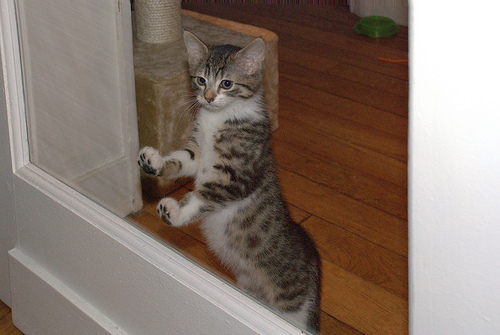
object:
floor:
[112, 1, 404, 334]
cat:
[135, 32, 319, 330]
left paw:
[156, 194, 178, 228]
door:
[2, 0, 415, 334]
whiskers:
[176, 87, 205, 118]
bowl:
[350, 15, 396, 40]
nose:
[204, 92, 216, 103]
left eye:
[220, 80, 234, 92]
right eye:
[196, 75, 207, 88]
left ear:
[240, 37, 267, 74]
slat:
[277, 77, 407, 137]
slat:
[280, 118, 409, 190]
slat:
[278, 60, 405, 121]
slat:
[276, 36, 415, 96]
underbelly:
[192, 118, 263, 291]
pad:
[142, 152, 147, 160]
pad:
[146, 158, 152, 166]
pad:
[162, 205, 168, 213]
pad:
[156, 205, 162, 215]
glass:
[13, 1, 411, 333]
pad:
[161, 213, 172, 225]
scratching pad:
[137, 1, 184, 42]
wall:
[348, 1, 411, 31]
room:
[18, 2, 409, 333]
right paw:
[135, 146, 162, 180]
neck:
[197, 99, 263, 126]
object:
[367, 52, 409, 65]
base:
[13, 149, 299, 334]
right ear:
[179, 32, 213, 63]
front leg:
[137, 117, 210, 180]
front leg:
[158, 134, 264, 229]